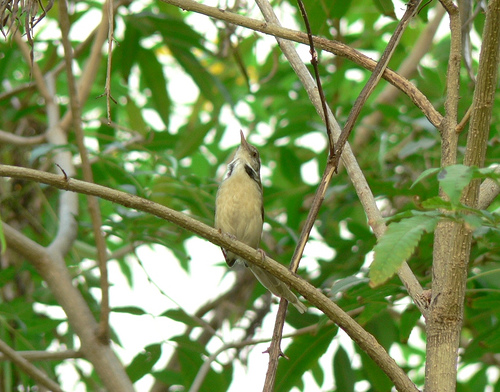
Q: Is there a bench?
A: No, there are no benches.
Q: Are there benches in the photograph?
A: No, there are no benches.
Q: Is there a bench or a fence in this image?
A: No, there are no benches or fences.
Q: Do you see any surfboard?
A: No, there are no surfboards.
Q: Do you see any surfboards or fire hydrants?
A: No, there are no surfboards or fire hydrants.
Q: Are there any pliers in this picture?
A: No, there are no pliers.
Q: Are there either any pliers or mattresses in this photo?
A: No, there are no pliers or mattresses.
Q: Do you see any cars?
A: No, there are no cars.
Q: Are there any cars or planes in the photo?
A: No, there are no cars or planes.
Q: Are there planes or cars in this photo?
A: No, there are no cars or planes.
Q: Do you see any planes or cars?
A: No, there are no cars or planes.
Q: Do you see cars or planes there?
A: No, there are no cars or planes.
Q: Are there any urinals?
A: No, there are no urinals.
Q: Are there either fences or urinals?
A: No, there are no urinals or fences.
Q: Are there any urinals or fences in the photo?
A: No, there are no urinals or fences.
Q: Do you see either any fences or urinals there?
A: No, there are no urinals or fences.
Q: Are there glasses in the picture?
A: No, there are no glasses.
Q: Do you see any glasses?
A: No, there are no glasses.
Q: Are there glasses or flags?
A: No, there are no glasses or flags.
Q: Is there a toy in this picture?
A: No, there are no toys.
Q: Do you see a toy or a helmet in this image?
A: No, there are no toys or helmets.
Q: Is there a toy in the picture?
A: No, there are no toys.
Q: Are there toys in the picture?
A: No, there are no toys.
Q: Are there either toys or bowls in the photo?
A: No, there are no toys or bowls.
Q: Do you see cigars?
A: No, there are no cigars.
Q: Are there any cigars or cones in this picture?
A: No, there are no cigars or cones.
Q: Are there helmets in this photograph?
A: No, there are no helmets.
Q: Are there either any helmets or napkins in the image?
A: No, there are no helmets or napkins.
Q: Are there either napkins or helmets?
A: No, there are no helmets or napkins.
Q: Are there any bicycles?
A: No, there are no bicycles.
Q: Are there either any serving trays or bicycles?
A: No, there are no bicycles or serving trays.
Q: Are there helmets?
A: No, there are no helmets.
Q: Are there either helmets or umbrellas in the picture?
A: No, there are no helmets or umbrellas.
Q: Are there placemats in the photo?
A: No, there are no placemats.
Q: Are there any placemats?
A: No, there are no placemats.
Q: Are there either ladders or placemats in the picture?
A: No, there are no placemats or ladders.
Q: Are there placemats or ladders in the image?
A: No, there are no placemats or ladders.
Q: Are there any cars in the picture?
A: No, there are no cars.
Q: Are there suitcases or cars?
A: No, there are no cars or suitcases.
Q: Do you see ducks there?
A: No, there are no ducks.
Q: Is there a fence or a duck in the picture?
A: No, there are no ducks or fences.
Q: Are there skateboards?
A: No, there are no skateboards.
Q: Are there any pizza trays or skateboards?
A: No, there are no skateboards or pizza trays.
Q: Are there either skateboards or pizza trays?
A: No, there are no skateboards or pizza trays.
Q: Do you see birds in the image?
A: Yes, there is a bird.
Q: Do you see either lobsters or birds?
A: Yes, there is a bird.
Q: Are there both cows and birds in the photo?
A: No, there is a bird but no cows.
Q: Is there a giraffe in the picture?
A: No, there are no giraffes.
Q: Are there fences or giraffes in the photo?
A: No, there are no giraffes or fences.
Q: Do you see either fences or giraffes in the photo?
A: No, there are no giraffes or fences.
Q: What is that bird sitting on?
A: The bird is sitting on the branch.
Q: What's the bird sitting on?
A: The bird is sitting on the branch.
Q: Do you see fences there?
A: No, there are no fences.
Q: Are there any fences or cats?
A: No, there are no fences or cats.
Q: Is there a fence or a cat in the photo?
A: No, there are no fences or cats.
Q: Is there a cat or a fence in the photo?
A: No, there are no fences or cats.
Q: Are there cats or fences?
A: No, there are no fences or cats.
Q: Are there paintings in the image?
A: No, there are no paintings.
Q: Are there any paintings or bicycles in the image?
A: No, there are no paintings or bicycles.